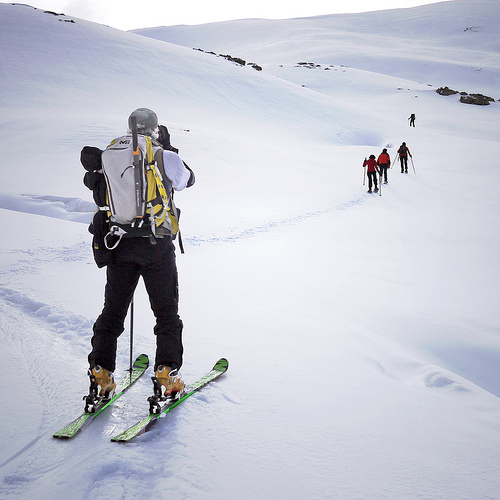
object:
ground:
[0, 0, 500, 500]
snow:
[2, 2, 498, 499]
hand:
[155, 125, 170, 146]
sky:
[0, 0, 445, 31]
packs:
[80, 146, 110, 269]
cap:
[128, 107, 159, 133]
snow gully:
[427, 359, 500, 397]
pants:
[86, 229, 183, 374]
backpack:
[101, 132, 179, 236]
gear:
[87, 135, 194, 373]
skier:
[85, 107, 195, 399]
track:
[315, 203, 362, 218]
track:
[1, 288, 82, 356]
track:
[0, 188, 91, 226]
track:
[209, 227, 251, 247]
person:
[397, 142, 413, 174]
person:
[362, 154, 382, 194]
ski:
[110, 358, 229, 445]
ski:
[373, 187, 380, 193]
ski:
[380, 180, 390, 187]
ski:
[404, 166, 409, 176]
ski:
[52, 353, 150, 442]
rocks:
[251, 65, 262, 72]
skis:
[366, 188, 372, 194]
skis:
[378, 177, 383, 185]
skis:
[400, 169, 404, 174]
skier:
[377, 148, 391, 184]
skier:
[408, 113, 416, 127]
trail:
[0, 191, 374, 443]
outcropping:
[459, 95, 490, 105]